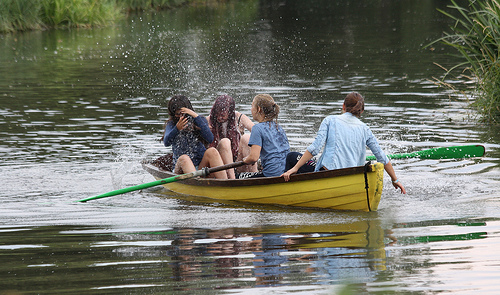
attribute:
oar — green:
[76, 155, 263, 212]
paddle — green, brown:
[80, 154, 260, 207]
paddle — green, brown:
[360, 132, 491, 182]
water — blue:
[240, 85, 288, 187]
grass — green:
[424, 1, 499, 138]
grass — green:
[0, 0, 188, 34]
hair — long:
[211, 93, 238, 160]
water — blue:
[1, 0, 499, 293]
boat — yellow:
[131, 152, 388, 204]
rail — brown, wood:
[137, 160, 362, 185]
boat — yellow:
[216, 165, 386, 222]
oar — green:
[81, 178, 153, 208]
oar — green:
[388, 127, 488, 172]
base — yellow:
[144, 174, 382, 219]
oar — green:
[76, 157, 250, 205]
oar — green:
[367, 142, 484, 164]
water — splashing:
[122, 173, 469, 241]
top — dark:
[162, 114, 215, 168]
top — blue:
[248, 122, 286, 175]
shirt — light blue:
[246, 125, 289, 174]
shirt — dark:
[163, 115, 215, 169]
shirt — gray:
[248, 123, 292, 179]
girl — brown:
[205, 96, 254, 176]